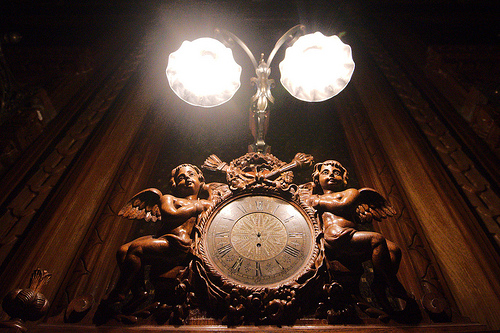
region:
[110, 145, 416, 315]
cherubs on either side of clock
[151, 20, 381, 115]
lamp with two sources of light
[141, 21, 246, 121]
bulb shining brightly in glass shade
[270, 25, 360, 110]
scalloped edge of lighting fixture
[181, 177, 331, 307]
roman numerals on clock face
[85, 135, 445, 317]
intricately carved wood around clock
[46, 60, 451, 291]
wall paneled in dark wood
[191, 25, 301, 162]
decorated metal support for lights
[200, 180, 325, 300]
clock without hands on face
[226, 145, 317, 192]
royal scepter on top of clock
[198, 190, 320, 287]
a clock in a wall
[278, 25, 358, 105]
a light shinning bright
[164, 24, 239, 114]
a light shinning bright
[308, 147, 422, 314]
a statue beside the clock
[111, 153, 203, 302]
a statue with wings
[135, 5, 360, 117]
lights shinning on the clock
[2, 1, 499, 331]
a picture taken at night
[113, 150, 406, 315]
statues besides a clock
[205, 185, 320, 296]
a rather old clock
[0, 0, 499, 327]
a night time scene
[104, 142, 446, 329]
Antique clock on a wall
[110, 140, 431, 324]
Clock has wooden decorations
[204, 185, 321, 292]
Clock has roman numbers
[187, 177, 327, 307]
Clock doesn't have hour hands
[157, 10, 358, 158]
Two bright lamps over the clock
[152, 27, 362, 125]
Lamps are turned on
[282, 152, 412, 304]
Angel statue with wings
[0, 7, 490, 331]
Clock is hang in a wooden wall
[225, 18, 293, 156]
Support of lights are metal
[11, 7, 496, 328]
Wall is brown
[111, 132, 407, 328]
Old clock is illuminated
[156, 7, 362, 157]
Two lamps above the clock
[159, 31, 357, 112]
Lamps are turn on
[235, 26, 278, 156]
Metal support holding the lamps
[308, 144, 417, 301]
Angel statue on right side of lamp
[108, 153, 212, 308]
Angel statue on left side of lamp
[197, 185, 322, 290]
Clock has roman numerals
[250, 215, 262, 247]
Clock has two wholes in the center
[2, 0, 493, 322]
Clock is on a wood wall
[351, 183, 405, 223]
Wing of angel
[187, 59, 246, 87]
light coming through ceiling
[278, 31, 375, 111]
circular hole in ceiling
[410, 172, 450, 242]
small stain on wood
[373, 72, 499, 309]
large brown wooden beams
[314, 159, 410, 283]
gold angel on side of cloc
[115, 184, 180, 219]
golden angel wings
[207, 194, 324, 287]
gold face on clock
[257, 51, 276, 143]
gold point on clock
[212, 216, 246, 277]
roman numerals on clock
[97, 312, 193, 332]
base on clock holder